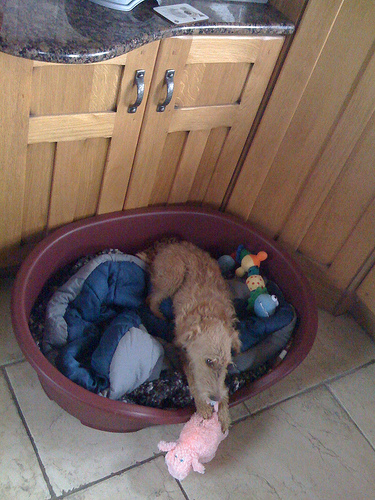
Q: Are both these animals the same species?
A: No, they are dogs and pigs.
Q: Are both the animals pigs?
A: No, they are dogs and pigs.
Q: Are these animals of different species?
A: Yes, they are dogs and pigs.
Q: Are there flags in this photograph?
A: No, there are no flags.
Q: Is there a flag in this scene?
A: No, there are no flags.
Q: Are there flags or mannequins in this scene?
A: No, there are no flags or mannequins.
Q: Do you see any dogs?
A: Yes, there is a dog.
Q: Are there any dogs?
A: Yes, there is a dog.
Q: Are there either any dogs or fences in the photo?
A: Yes, there is a dog.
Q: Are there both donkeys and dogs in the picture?
A: No, there is a dog but no donkeys.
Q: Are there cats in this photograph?
A: No, there are no cats.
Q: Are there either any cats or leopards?
A: No, there are no cats or leopards.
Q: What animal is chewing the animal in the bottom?
A: The dog is chewing the pig.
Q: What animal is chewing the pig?
A: The dog is chewing the pig.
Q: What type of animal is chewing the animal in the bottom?
A: The animal is a dog.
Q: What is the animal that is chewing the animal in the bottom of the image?
A: The animal is a dog.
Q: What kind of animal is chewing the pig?
A: The animal is a dog.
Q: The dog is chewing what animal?
A: The dog is chewing the pig.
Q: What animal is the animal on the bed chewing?
A: The dog is chewing the pig.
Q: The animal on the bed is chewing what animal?
A: The dog is chewing the pig.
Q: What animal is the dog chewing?
A: The dog is chewing the pig.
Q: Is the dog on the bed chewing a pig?
A: Yes, the dog is chewing a pig.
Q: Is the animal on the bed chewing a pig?
A: Yes, the dog is chewing a pig.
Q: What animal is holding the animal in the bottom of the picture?
A: The dog is holding the pig.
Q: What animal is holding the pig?
A: The dog is holding the pig.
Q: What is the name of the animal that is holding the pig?
A: The animal is a dog.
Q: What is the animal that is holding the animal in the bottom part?
A: The animal is a dog.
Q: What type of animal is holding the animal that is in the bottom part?
A: The animal is a dog.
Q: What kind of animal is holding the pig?
A: The animal is a dog.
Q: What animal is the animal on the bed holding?
A: The dog is holding the pig.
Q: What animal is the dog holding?
A: The dog is holding the pig.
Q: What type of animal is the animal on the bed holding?
A: The dog is holding the pig.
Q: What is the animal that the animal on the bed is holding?
A: The animal is a pig.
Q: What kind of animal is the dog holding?
A: The dog is holding the pig.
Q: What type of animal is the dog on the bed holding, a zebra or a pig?
A: The dog is holding a pig.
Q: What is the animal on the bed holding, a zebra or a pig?
A: The dog is holding a pig.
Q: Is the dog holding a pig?
A: Yes, the dog is holding a pig.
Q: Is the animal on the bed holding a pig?
A: Yes, the dog is holding a pig.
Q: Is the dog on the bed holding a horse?
A: No, the dog is holding a pig.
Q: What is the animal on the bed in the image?
A: The animal is a dog.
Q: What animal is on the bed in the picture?
A: The animal is a dog.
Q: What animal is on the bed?
A: The animal is a dog.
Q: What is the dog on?
A: The dog is on the bed.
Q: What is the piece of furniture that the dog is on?
A: The piece of furniture is a bed.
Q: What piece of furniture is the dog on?
A: The dog is on the bed.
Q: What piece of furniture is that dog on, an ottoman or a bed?
A: The dog is on a bed.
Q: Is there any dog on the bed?
A: Yes, there is a dog on the bed.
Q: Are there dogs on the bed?
A: Yes, there is a dog on the bed.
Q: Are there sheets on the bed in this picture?
A: No, there is a dog on the bed.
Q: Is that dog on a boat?
A: No, the dog is on a bed.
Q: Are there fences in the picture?
A: No, there are no fences.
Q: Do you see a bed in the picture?
A: Yes, there is a bed.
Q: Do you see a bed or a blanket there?
A: Yes, there is a bed.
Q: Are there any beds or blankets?
A: Yes, there is a bed.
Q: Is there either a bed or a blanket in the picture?
A: Yes, there is a bed.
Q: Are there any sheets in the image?
A: No, there are no sheets.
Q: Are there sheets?
A: No, there are no sheets.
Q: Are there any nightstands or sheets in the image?
A: No, there are no sheets or nightstands.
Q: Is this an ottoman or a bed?
A: This is a bed.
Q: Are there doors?
A: Yes, there is a door.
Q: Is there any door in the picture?
A: Yes, there is a door.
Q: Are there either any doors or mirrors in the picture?
A: Yes, there is a door.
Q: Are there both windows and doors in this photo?
A: No, there is a door but no windows.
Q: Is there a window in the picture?
A: No, there are no windows.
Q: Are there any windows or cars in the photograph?
A: No, there are no windows or cars.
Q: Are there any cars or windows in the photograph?
A: No, there are no windows or cars.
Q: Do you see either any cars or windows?
A: No, there are no windows or cars.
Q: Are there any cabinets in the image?
A: Yes, there is a cabinet.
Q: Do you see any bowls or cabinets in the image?
A: Yes, there is a cabinet.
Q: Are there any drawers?
A: No, there are no drawers.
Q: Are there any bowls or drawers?
A: No, there are no drawers or bowls.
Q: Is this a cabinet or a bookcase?
A: This is a cabinet.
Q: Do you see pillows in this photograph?
A: No, there are no pillows.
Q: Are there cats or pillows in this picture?
A: No, there are no pillows or cats.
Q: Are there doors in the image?
A: Yes, there are doors.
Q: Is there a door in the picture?
A: Yes, there are doors.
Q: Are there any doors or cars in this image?
A: Yes, there are doors.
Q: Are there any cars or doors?
A: Yes, there are doors.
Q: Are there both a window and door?
A: No, there are doors but no windows.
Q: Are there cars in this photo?
A: No, there are no cars.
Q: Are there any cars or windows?
A: No, there are no cars or windows.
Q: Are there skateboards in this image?
A: No, there are no skateboards.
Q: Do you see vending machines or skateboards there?
A: No, there are no skateboards or vending machines.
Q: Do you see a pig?
A: Yes, there is a pig.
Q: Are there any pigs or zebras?
A: Yes, there is a pig.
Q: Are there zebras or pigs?
A: Yes, there is a pig.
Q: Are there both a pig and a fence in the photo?
A: No, there is a pig but no fences.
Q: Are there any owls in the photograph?
A: No, there are no owls.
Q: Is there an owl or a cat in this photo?
A: No, there are no owls or cats.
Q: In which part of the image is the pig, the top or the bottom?
A: The pig is in the bottom of the image.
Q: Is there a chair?
A: No, there are no chairs.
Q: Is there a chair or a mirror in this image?
A: No, there are no chairs or mirrors.